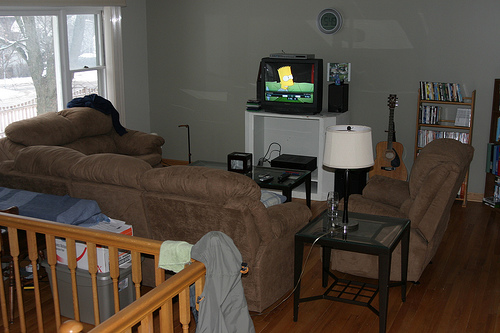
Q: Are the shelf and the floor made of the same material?
A: Yes, both the shelf and the floor are made of wood.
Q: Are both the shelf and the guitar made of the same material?
A: Yes, both the shelf and the guitar are made of wood.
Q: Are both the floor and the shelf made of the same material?
A: Yes, both the floor and the shelf are made of wood.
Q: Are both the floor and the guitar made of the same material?
A: Yes, both the floor and the guitar are made of wood.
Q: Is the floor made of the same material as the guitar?
A: Yes, both the floor and the guitar are made of wood.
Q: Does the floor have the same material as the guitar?
A: Yes, both the floor and the guitar are made of wood.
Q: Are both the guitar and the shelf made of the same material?
A: Yes, both the guitar and the shelf are made of wood.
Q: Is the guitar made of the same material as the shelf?
A: Yes, both the guitar and the shelf are made of wood.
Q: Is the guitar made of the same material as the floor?
A: Yes, both the guitar and the floor are made of wood.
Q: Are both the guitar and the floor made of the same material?
A: Yes, both the guitar and the floor are made of wood.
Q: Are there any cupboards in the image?
A: No, there are no cupboards.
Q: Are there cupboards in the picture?
A: No, there are no cupboards.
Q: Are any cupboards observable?
A: No, there are no cupboards.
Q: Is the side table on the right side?
A: Yes, the side table is on the right of the image.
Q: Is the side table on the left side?
A: No, the side table is on the right of the image.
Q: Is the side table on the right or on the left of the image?
A: The side table is on the right of the image.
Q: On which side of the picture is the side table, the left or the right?
A: The side table is on the right of the image.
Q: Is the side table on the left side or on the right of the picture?
A: The side table is on the right of the image.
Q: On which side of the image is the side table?
A: The side table is on the right of the image.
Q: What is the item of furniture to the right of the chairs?
A: The piece of furniture is a side table.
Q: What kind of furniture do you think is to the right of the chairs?
A: The piece of furniture is a side table.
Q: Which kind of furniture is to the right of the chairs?
A: The piece of furniture is a side table.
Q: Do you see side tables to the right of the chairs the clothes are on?
A: Yes, there is a side table to the right of the chairs.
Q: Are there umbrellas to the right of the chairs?
A: No, there is a side table to the right of the chairs.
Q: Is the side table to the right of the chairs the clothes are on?
A: Yes, the side table is to the right of the chairs.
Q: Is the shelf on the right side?
A: Yes, the shelf is on the right of the image.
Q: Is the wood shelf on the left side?
A: No, the shelf is on the right of the image.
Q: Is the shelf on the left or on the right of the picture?
A: The shelf is on the right of the image.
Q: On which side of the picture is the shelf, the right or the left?
A: The shelf is on the right of the image.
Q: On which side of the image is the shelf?
A: The shelf is on the right of the image.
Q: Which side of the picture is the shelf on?
A: The shelf is on the right of the image.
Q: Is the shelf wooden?
A: Yes, the shelf is wooden.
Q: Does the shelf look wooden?
A: Yes, the shelf is wooden.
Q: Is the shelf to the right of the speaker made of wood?
A: Yes, the shelf is made of wood.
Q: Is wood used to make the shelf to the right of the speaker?
A: Yes, the shelf is made of wood.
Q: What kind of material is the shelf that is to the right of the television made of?
A: The shelf is made of wood.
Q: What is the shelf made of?
A: The shelf is made of wood.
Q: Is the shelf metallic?
A: No, the shelf is wooden.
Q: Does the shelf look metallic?
A: No, the shelf is wooden.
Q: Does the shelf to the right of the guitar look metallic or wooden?
A: The shelf is wooden.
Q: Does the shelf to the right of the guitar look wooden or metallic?
A: The shelf is wooden.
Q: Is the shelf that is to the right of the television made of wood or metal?
A: The shelf is made of wood.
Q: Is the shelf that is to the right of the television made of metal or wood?
A: The shelf is made of wood.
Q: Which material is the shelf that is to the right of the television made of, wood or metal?
A: The shelf is made of wood.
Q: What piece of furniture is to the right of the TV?
A: The piece of furniture is a shelf.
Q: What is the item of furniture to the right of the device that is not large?
A: The piece of furniture is a shelf.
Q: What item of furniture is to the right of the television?
A: The piece of furniture is a shelf.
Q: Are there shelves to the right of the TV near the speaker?
A: Yes, there is a shelf to the right of the television.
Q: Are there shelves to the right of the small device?
A: Yes, there is a shelf to the right of the television.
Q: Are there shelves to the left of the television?
A: No, the shelf is to the right of the television.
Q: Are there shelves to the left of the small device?
A: No, the shelf is to the right of the television.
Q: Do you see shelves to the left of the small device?
A: No, the shelf is to the right of the television.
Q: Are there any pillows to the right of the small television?
A: No, there is a shelf to the right of the television.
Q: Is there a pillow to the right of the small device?
A: No, there is a shelf to the right of the television.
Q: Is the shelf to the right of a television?
A: Yes, the shelf is to the right of a television.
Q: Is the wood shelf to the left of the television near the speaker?
A: No, the shelf is to the right of the television.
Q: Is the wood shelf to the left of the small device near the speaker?
A: No, the shelf is to the right of the television.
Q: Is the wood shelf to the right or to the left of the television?
A: The shelf is to the right of the television.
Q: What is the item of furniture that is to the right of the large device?
A: The piece of furniture is a shelf.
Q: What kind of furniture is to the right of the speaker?
A: The piece of furniture is a shelf.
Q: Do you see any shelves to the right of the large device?
A: Yes, there is a shelf to the right of the speaker.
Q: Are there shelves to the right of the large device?
A: Yes, there is a shelf to the right of the speaker.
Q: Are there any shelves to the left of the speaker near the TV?
A: No, the shelf is to the right of the speaker.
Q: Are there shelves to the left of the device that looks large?
A: No, the shelf is to the right of the speaker.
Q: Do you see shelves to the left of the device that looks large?
A: No, the shelf is to the right of the speaker.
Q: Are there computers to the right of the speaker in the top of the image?
A: No, there is a shelf to the right of the speaker.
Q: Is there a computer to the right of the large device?
A: No, there is a shelf to the right of the speaker.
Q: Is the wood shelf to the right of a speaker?
A: Yes, the shelf is to the right of a speaker.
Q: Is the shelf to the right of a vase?
A: No, the shelf is to the right of a speaker.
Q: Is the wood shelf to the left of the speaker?
A: No, the shelf is to the right of the speaker.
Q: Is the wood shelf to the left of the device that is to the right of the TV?
A: No, the shelf is to the right of the speaker.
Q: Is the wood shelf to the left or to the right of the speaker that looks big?
A: The shelf is to the right of the speaker.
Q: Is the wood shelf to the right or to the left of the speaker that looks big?
A: The shelf is to the right of the speaker.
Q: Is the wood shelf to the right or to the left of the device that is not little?
A: The shelf is to the right of the speaker.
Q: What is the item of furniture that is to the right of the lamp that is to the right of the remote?
A: The piece of furniture is a shelf.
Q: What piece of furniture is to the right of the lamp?
A: The piece of furniture is a shelf.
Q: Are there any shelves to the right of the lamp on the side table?
A: Yes, there is a shelf to the right of the lamp.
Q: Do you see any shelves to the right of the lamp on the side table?
A: Yes, there is a shelf to the right of the lamp.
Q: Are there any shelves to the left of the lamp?
A: No, the shelf is to the right of the lamp.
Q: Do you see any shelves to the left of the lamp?
A: No, the shelf is to the right of the lamp.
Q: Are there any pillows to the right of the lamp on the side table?
A: No, there is a shelf to the right of the lamp.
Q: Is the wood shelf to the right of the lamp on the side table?
A: Yes, the shelf is to the right of the lamp.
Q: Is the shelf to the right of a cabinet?
A: No, the shelf is to the right of the lamp.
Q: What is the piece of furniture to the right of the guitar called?
A: The piece of furniture is a shelf.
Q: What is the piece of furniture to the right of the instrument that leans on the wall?
A: The piece of furniture is a shelf.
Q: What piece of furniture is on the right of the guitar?
A: The piece of furniture is a shelf.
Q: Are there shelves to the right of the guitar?
A: Yes, there is a shelf to the right of the guitar.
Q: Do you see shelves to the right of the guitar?
A: Yes, there is a shelf to the right of the guitar.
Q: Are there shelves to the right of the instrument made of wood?
A: Yes, there is a shelf to the right of the guitar.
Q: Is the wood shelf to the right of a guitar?
A: Yes, the shelf is to the right of a guitar.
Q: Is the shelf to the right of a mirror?
A: No, the shelf is to the right of a guitar.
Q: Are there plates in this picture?
A: No, there are no plates.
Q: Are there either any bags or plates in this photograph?
A: No, there are no plates or bags.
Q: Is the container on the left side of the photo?
A: Yes, the container is on the left of the image.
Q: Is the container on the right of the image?
A: No, the container is on the left of the image.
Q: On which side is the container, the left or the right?
A: The container is on the left of the image.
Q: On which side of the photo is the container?
A: The container is on the left of the image.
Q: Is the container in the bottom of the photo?
A: Yes, the container is in the bottom of the image.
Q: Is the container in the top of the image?
A: No, the container is in the bottom of the image.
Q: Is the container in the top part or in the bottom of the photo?
A: The container is in the bottom of the image.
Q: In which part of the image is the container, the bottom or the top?
A: The container is in the bottom of the image.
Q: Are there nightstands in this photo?
A: No, there are no nightstands.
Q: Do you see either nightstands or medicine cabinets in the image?
A: No, there are no nightstands or medicine cabinets.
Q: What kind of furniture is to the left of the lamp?
A: The pieces of furniture are chairs.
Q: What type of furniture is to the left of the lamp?
A: The pieces of furniture are chairs.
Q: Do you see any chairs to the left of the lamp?
A: Yes, there are chairs to the left of the lamp.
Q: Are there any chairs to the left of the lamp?
A: Yes, there are chairs to the left of the lamp.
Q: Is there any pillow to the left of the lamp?
A: No, there are chairs to the left of the lamp.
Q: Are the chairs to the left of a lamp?
A: Yes, the chairs are to the left of a lamp.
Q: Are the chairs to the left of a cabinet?
A: No, the chairs are to the left of a lamp.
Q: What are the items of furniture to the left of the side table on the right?
A: The pieces of furniture are chairs.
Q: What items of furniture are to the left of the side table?
A: The pieces of furniture are chairs.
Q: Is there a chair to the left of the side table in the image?
A: Yes, there are chairs to the left of the side table.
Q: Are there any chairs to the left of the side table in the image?
A: Yes, there are chairs to the left of the side table.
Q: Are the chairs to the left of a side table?
A: Yes, the chairs are to the left of a side table.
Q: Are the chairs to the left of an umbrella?
A: No, the chairs are to the left of a side table.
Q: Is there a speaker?
A: Yes, there is a speaker.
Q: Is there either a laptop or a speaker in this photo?
A: Yes, there is a speaker.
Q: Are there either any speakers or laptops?
A: Yes, there is a speaker.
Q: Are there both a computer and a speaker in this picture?
A: No, there is a speaker but no computers.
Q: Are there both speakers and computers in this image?
A: No, there is a speaker but no computers.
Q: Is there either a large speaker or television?
A: Yes, there is a large speaker.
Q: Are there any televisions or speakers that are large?
A: Yes, the speaker is large.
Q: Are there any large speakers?
A: Yes, there is a large speaker.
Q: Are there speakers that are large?
A: Yes, there is a speaker that is large.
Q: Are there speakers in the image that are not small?
A: Yes, there is a large speaker.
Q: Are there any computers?
A: No, there are no computers.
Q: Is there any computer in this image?
A: No, there are no computers.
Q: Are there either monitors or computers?
A: No, there are no computers or monitors.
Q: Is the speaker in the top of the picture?
A: Yes, the speaker is in the top of the image.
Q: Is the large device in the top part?
A: Yes, the speaker is in the top of the image.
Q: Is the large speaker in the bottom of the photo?
A: No, the speaker is in the top of the image.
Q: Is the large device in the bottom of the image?
A: No, the speaker is in the top of the image.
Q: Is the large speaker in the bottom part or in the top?
A: The speaker is in the top of the image.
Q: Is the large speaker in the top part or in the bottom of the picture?
A: The speaker is in the top of the image.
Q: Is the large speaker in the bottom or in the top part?
A: The speaker is in the top of the image.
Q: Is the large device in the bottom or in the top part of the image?
A: The speaker is in the top of the image.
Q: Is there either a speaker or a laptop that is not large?
A: No, there is a speaker but it is large.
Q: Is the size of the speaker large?
A: Yes, the speaker is large.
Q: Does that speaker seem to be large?
A: Yes, the speaker is large.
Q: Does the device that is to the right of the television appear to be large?
A: Yes, the speaker is large.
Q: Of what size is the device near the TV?
A: The speaker is large.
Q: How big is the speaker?
A: The speaker is large.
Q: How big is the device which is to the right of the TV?
A: The speaker is large.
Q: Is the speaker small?
A: No, the speaker is large.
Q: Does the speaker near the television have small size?
A: No, the speaker is large.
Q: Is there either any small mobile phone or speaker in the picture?
A: No, there is a speaker but it is large.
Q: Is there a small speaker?
A: No, there is a speaker but it is large.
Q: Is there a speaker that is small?
A: No, there is a speaker but it is large.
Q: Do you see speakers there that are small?
A: No, there is a speaker but it is large.